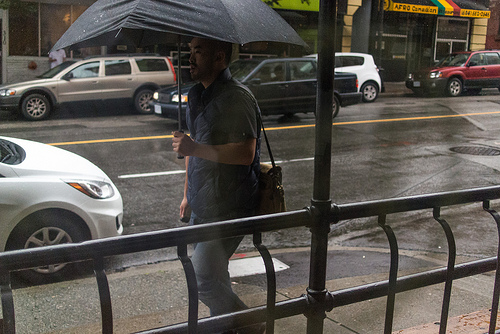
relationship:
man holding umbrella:
[169, 34, 261, 333] [44, 1, 312, 53]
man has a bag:
[169, 34, 261, 333] [248, 92, 287, 220]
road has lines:
[0, 90, 498, 332] [40, 106, 499, 178]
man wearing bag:
[169, 34, 261, 333] [248, 92, 287, 220]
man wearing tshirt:
[169, 34, 261, 333] [183, 70, 263, 232]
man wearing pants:
[169, 34, 261, 333] [189, 216, 256, 330]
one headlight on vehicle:
[1, 87, 20, 101] [2, 51, 178, 121]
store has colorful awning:
[341, 0, 491, 58] [380, 1, 493, 21]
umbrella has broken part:
[44, 1, 312, 53] [113, 26, 126, 40]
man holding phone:
[169, 34, 261, 333] [181, 201, 192, 222]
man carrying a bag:
[169, 34, 261, 333] [248, 92, 287, 220]